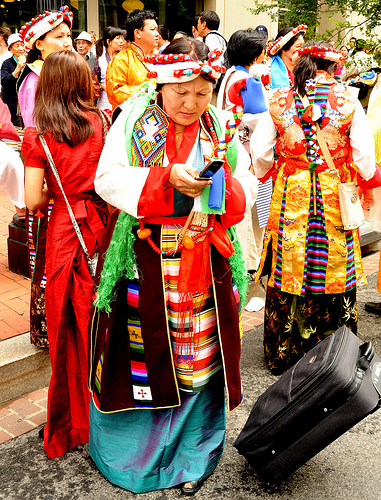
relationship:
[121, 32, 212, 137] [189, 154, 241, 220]
woman with phone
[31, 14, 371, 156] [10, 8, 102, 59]
women with headdress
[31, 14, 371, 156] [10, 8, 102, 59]
women are wearing headdress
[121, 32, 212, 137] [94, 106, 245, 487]
woman wearing costume